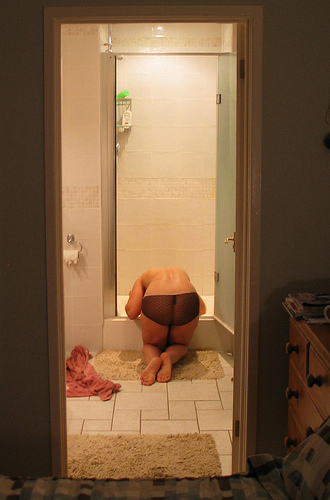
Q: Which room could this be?
A: It is a bathroom.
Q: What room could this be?
A: It is a bathroom.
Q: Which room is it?
A: It is a bathroom.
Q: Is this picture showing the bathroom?
A: Yes, it is showing the bathroom.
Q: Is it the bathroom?
A: Yes, it is the bathroom.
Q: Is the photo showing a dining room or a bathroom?
A: It is showing a bathroom.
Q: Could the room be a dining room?
A: No, it is a bathroom.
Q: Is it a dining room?
A: No, it is a bathroom.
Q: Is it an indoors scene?
A: Yes, it is indoors.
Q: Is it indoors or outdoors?
A: It is indoors.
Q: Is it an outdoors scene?
A: No, it is indoors.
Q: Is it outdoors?
A: No, it is indoors.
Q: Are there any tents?
A: No, there are no tents.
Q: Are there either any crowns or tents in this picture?
A: No, there are no tents or crowns.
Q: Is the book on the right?
A: Yes, the book is on the right of the image.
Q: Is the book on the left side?
A: No, the book is on the right of the image.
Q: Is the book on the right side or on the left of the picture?
A: The book is on the right of the image.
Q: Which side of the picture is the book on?
A: The book is on the right of the image.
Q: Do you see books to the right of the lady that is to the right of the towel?
A: Yes, there is a book to the right of the lady.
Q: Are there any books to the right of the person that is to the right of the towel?
A: Yes, there is a book to the right of the lady.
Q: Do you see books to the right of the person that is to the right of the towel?
A: Yes, there is a book to the right of the lady.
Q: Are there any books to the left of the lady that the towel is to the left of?
A: No, the book is to the right of the lady.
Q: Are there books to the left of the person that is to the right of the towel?
A: No, the book is to the right of the lady.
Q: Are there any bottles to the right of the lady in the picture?
A: No, there is a book to the right of the lady.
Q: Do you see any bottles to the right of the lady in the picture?
A: No, there is a book to the right of the lady.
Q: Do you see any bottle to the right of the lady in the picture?
A: No, there is a book to the right of the lady.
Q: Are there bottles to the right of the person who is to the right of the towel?
A: No, there is a book to the right of the lady.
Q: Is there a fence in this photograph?
A: No, there are no fences.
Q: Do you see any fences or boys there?
A: No, there are no fences or boys.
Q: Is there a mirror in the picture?
A: No, there are no mirrors.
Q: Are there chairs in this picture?
A: No, there are no chairs.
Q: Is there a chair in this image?
A: No, there are no chairs.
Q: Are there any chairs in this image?
A: No, there are no chairs.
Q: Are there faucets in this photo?
A: No, there are no faucets.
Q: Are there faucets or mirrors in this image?
A: No, there are no faucets or mirrors.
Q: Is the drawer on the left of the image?
A: No, the drawer is on the right of the image.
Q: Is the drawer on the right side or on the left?
A: The drawer is on the right of the image.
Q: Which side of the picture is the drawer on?
A: The drawer is on the right of the image.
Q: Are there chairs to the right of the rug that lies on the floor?
A: No, there is a drawer to the right of the rug.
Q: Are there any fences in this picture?
A: No, there are no fences.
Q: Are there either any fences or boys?
A: No, there are no fences or boys.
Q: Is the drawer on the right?
A: Yes, the drawer is on the right of the image.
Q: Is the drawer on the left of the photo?
A: No, the drawer is on the right of the image.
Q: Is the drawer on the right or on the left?
A: The drawer is on the right of the image.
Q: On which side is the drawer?
A: The drawer is on the right of the image.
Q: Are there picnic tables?
A: No, there are no picnic tables.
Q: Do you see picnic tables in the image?
A: No, there are no picnic tables.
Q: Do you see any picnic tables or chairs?
A: No, there are no picnic tables or chairs.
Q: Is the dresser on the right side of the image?
A: Yes, the dresser is on the right of the image.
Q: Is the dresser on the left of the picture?
A: No, the dresser is on the right of the image.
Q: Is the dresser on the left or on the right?
A: The dresser is on the right of the image.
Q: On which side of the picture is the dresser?
A: The dresser is on the right of the image.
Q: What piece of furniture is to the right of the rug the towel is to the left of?
A: The piece of furniture is a dresser.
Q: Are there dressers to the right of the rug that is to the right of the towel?
A: Yes, there is a dresser to the right of the rug.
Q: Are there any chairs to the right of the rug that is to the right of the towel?
A: No, there is a dresser to the right of the rug.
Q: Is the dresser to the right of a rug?
A: Yes, the dresser is to the right of a rug.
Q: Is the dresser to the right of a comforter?
A: No, the dresser is to the right of a rug.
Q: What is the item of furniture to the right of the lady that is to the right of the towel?
A: The piece of furniture is a dresser.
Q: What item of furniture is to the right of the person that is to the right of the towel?
A: The piece of furniture is a dresser.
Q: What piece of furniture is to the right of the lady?
A: The piece of furniture is a dresser.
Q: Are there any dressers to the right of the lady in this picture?
A: Yes, there is a dresser to the right of the lady.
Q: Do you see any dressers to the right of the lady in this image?
A: Yes, there is a dresser to the right of the lady.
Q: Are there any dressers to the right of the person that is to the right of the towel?
A: Yes, there is a dresser to the right of the lady.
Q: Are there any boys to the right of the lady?
A: No, there is a dresser to the right of the lady.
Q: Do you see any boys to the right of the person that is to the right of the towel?
A: No, there is a dresser to the right of the lady.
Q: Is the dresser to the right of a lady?
A: Yes, the dresser is to the right of a lady.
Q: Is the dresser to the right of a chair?
A: No, the dresser is to the right of a lady.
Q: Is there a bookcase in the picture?
A: No, there are no bookcases.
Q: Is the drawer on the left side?
A: No, the drawer is on the right of the image.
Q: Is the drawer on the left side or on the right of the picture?
A: The drawer is on the right of the image.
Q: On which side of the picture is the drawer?
A: The drawer is on the right of the image.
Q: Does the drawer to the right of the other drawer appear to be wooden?
A: Yes, the drawer is wooden.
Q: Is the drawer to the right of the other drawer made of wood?
A: Yes, the drawer is made of wood.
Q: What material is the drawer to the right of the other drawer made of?
A: The drawer is made of wood.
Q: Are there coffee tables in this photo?
A: No, there are no coffee tables.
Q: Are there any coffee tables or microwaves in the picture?
A: No, there are no coffee tables or microwaves.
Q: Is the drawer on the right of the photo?
A: Yes, the drawer is on the right of the image.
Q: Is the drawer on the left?
A: No, the drawer is on the right of the image.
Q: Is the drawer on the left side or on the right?
A: The drawer is on the right of the image.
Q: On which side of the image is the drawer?
A: The drawer is on the right of the image.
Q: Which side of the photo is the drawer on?
A: The drawer is on the right of the image.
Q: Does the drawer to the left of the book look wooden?
A: Yes, the drawer is wooden.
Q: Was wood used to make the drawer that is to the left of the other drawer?
A: Yes, the drawer is made of wood.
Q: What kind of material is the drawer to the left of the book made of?
A: The drawer is made of wood.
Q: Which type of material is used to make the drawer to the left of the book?
A: The drawer is made of wood.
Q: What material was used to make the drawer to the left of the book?
A: The drawer is made of wood.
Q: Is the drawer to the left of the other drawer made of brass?
A: No, the drawer is made of wood.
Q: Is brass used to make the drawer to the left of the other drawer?
A: No, the drawer is made of wood.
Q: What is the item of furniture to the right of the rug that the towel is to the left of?
A: The piece of furniture is a drawer.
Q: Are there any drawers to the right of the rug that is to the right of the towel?
A: Yes, there is a drawer to the right of the rug.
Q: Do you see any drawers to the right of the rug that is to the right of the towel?
A: Yes, there is a drawer to the right of the rug.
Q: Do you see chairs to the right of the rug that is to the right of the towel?
A: No, there is a drawer to the right of the rug.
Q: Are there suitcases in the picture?
A: No, there are no suitcases.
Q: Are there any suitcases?
A: No, there are no suitcases.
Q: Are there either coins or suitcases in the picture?
A: No, there are no suitcases or coins.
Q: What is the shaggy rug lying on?
A: The rug is lying on the floor.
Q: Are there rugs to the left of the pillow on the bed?
A: Yes, there is a rug to the left of the pillow.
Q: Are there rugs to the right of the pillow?
A: No, the rug is to the left of the pillow.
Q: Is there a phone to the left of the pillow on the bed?
A: No, there is a rug to the left of the pillow.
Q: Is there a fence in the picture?
A: No, there are no fences.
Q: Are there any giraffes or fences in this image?
A: No, there are no fences or giraffes.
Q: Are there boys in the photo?
A: No, there are no boys.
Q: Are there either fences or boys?
A: No, there are no boys or fences.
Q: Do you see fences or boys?
A: No, there are no boys or fences.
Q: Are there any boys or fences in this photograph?
A: No, there are no boys or fences.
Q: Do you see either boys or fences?
A: No, there are no boys or fences.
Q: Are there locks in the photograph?
A: No, there are no locks.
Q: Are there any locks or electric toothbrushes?
A: No, there are no locks or electric toothbrushes.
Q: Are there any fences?
A: No, there are no fences.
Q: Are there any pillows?
A: Yes, there is a pillow.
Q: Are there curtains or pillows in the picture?
A: Yes, there is a pillow.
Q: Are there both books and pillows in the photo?
A: Yes, there are both a pillow and a book.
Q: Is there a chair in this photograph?
A: No, there are no chairs.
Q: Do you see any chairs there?
A: No, there are no chairs.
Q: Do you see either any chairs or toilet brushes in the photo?
A: No, there are no chairs or toilet brushes.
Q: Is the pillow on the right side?
A: Yes, the pillow is on the right of the image.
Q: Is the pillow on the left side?
A: No, the pillow is on the right of the image.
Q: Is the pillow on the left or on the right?
A: The pillow is on the right of the image.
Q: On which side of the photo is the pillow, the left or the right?
A: The pillow is on the right of the image.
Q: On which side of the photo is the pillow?
A: The pillow is on the right of the image.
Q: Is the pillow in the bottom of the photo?
A: Yes, the pillow is in the bottom of the image.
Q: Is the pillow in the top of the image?
A: No, the pillow is in the bottom of the image.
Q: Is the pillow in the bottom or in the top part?
A: The pillow is in the bottom of the image.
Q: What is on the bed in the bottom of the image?
A: The pillow is on the bed.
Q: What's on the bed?
A: The pillow is on the bed.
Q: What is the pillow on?
A: The pillow is on the bed.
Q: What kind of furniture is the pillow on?
A: The pillow is on the bed.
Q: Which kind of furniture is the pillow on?
A: The pillow is on the bed.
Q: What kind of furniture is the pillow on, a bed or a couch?
A: The pillow is on a bed.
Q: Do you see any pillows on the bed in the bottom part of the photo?
A: Yes, there is a pillow on the bed.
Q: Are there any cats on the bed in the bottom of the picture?
A: No, there is a pillow on the bed.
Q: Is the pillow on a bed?
A: Yes, the pillow is on a bed.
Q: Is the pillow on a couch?
A: No, the pillow is on a bed.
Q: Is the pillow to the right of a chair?
A: No, the pillow is to the right of the rug.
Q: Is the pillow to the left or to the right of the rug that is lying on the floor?
A: The pillow is to the right of the rug.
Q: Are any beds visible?
A: Yes, there is a bed.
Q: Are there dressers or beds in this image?
A: Yes, there is a bed.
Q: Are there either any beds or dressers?
A: Yes, there is a bed.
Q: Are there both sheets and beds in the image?
A: No, there is a bed but no sheets.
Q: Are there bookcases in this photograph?
A: No, there are no bookcases.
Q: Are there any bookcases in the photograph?
A: No, there are no bookcases.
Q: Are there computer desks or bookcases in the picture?
A: No, there are no bookcases or computer desks.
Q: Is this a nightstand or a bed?
A: This is a bed.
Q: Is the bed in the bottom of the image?
A: Yes, the bed is in the bottom of the image.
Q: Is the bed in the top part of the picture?
A: No, the bed is in the bottom of the image.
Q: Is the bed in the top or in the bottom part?
A: The bed is in the bottom of the image.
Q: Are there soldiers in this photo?
A: No, there are no soldiers.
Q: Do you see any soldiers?
A: No, there are no soldiers.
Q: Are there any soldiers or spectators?
A: No, there are no soldiers or spectators.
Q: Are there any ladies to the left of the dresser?
A: Yes, there is a lady to the left of the dresser.